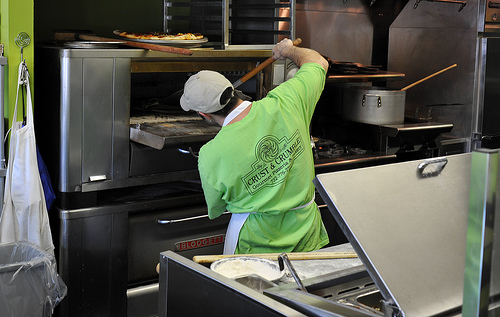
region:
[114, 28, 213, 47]
pizza in pan on top of oven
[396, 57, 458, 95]
wooden spoon in pot on stove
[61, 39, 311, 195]
metal pizza oven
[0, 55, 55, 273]
apron hanging on hook on left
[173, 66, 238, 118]
tab basebakk cap man is wearing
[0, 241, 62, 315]
trash can with plastic liner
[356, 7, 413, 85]
chimney vent from stove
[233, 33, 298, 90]
wooden paddle in man's hand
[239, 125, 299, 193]
company name and logo on shirt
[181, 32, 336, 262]
man taking pizza from oven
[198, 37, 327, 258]
back of person in green shirt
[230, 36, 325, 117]
hand on wood handle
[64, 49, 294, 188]
open door of oven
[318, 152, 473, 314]
handle on metal door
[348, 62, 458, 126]
handle in metal pot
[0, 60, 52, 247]
apron hanging on hook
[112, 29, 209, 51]
pizza on metal tray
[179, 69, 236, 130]
back of cap on head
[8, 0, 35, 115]
green wall with hook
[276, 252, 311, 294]
handle of metal ladle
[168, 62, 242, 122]
A man in a white hat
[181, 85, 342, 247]
A man in a green shirt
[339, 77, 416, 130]
A metal pot on a shelf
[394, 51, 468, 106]
A wooden stirrer in a pot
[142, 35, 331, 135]
A man making pizza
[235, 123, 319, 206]
Crust and Crumble sign on a shirt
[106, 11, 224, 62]
A pizza on top of oven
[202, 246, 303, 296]
A plate of flour on table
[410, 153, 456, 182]
Handle to metal door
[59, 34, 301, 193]
A metal pizza oven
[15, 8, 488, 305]
man working in commercial kitchen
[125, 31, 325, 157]
man holding handle in front of open oven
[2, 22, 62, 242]
apron hanging from green wall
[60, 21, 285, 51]
pizza and paddle on top of oven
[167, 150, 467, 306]
open metal lid above container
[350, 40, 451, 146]
large pot with utensil on top of stove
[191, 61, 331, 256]
green t-shirt with business name and information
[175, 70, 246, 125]
man in cap looking into dark oven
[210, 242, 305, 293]
plate next to curved metal handle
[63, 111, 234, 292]
closed oven under open oven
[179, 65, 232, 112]
man wearing a white cap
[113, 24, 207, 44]
a pizza on a metal plate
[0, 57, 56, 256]
a white apron on a hook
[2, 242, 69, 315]
a gray wastebasket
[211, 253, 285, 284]
a plate on a metal surface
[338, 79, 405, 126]
a metal pot on a metal counter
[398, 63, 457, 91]
wooden handle of a ladle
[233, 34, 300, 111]
man holding a wooden stick in his hand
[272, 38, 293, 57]
man wearing a plastic glove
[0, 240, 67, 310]
a plastic bag on a wastebasket